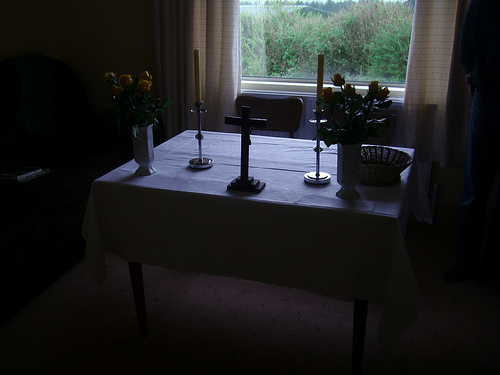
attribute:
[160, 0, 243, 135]
curtain — white, open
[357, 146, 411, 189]
basket — wicker, small, empty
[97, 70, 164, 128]
flowers — roses, yellow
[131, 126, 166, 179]
vase — white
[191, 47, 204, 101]
candle — yellow, tall, unlit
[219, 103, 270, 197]
crucifix — cross, brown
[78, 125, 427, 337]
table cloth — white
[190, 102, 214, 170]
candle holder — silver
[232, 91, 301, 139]
chair — wooden